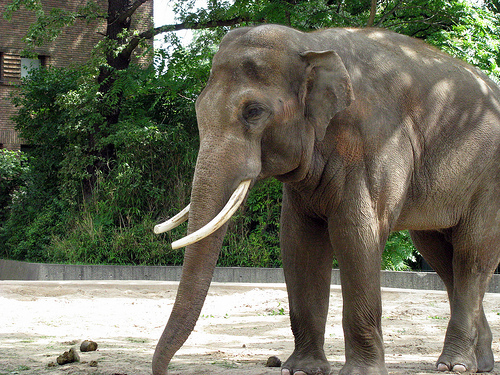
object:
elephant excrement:
[53, 343, 83, 367]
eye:
[240, 98, 270, 122]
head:
[187, 21, 357, 190]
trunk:
[142, 170, 257, 375]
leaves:
[277, 303, 287, 317]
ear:
[295, 43, 359, 143]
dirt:
[0, 279, 500, 375]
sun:
[0, 290, 177, 344]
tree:
[0, 0, 499, 270]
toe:
[434, 361, 449, 373]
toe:
[451, 362, 468, 374]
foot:
[430, 340, 481, 375]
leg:
[324, 166, 388, 375]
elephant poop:
[76, 336, 102, 352]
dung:
[49, 344, 85, 367]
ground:
[0, 276, 500, 375]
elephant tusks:
[167, 176, 252, 252]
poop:
[46, 333, 110, 372]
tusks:
[153, 199, 198, 234]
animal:
[135, 13, 500, 375]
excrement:
[261, 351, 282, 371]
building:
[0, 0, 161, 170]